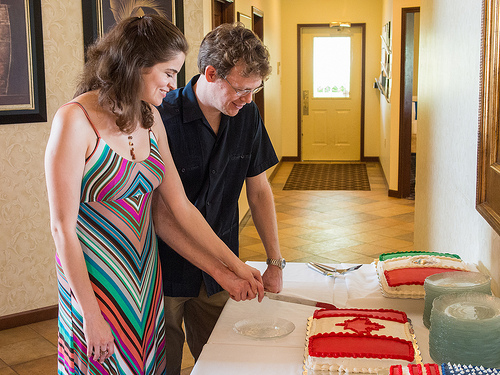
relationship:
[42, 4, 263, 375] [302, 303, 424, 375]
woman cutting cake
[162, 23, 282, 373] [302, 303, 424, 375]
man cutting cake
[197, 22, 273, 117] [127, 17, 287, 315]
head of man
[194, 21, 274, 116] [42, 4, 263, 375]
head of woman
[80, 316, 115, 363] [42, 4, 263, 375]
hand of woman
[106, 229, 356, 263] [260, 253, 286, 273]
watch on wrist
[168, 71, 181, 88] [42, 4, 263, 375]
nose of woman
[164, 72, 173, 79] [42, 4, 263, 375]
eye of woman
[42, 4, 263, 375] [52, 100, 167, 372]
woman wearing dress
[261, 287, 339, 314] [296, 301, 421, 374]
knife about to cut cake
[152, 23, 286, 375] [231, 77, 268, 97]
man wearing glasses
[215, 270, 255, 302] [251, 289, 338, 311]
hand holding knife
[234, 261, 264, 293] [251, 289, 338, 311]
hand holding knife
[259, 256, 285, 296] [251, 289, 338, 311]
hand holding knife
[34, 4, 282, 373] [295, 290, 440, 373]
couple cutting cake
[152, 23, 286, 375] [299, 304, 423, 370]
man cuts cake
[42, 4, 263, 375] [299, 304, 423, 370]
woman cuts cake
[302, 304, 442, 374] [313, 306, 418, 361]
cake has canada flag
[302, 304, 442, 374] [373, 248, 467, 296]
cake has frosting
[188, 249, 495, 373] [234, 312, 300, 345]
table has plate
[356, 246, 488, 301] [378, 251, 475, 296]
cake has frosting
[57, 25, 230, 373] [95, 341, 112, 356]
woman has ring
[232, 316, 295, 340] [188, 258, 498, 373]
plate on cloth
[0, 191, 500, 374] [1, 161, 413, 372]
floor on floor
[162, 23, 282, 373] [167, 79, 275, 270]
man wearing shirt